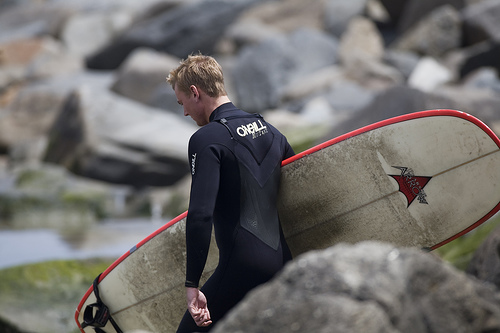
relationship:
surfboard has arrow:
[77, 108, 498, 332] [392, 173, 431, 207]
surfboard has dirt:
[77, 108, 498, 332] [121, 127, 443, 332]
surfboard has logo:
[77, 108, 498, 332] [388, 164, 430, 211]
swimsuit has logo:
[175, 105, 293, 332] [236, 118, 268, 140]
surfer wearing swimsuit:
[166, 53, 294, 332] [175, 105, 293, 332]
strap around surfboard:
[83, 273, 121, 332] [77, 108, 498, 332]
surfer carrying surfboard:
[166, 53, 294, 332] [77, 108, 498, 332]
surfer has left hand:
[166, 53, 294, 332] [187, 289, 211, 324]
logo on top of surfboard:
[388, 164, 430, 211] [77, 108, 498, 332]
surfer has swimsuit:
[166, 53, 294, 332] [175, 105, 293, 332]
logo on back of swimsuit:
[388, 164, 430, 211] [175, 105, 293, 332]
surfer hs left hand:
[166, 53, 294, 332] [187, 289, 211, 324]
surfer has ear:
[166, 53, 294, 332] [188, 84, 202, 103]